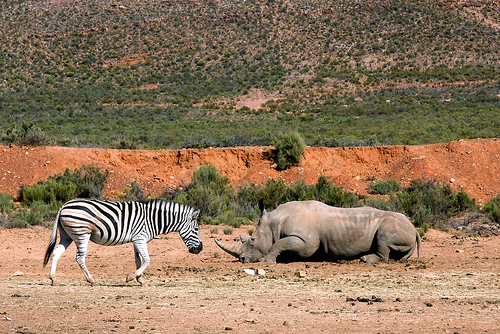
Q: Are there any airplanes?
A: No, there are no airplanes.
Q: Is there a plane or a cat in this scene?
A: No, there are no airplanes or cats.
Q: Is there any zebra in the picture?
A: Yes, there is a zebra.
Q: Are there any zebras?
A: Yes, there is a zebra.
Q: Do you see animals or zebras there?
A: Yes, there is a zebra.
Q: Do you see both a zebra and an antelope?
A: No, there is a zebra but no antelopes.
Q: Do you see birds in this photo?
A: No, there are no birds.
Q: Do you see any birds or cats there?
A: No, there are no birds or cats.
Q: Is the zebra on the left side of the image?
A: Yes, the zebra is on the left of the image.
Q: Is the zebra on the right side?
A: No, the zebra is on the left of the image.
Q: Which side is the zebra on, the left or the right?
A: The zebra is on the left of the image.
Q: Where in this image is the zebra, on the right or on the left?
A: The zebra is on the left of the image.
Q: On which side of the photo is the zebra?
A: The zebra is on the left of the image.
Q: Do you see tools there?
A: No, there are no tools.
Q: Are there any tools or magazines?
A: No, there are no tools or magazines.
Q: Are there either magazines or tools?
A: No, there are no tools or magazines.